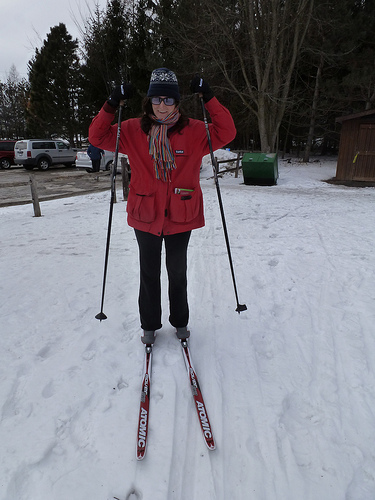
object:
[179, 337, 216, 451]
ski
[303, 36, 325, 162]
trunk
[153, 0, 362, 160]
tree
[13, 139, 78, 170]
car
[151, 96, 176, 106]
sunglasses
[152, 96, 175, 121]
face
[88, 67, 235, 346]
woman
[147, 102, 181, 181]
scarf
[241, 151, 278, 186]
trash bin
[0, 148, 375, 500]
snow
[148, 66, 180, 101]
hat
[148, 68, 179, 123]
head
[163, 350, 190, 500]
tracks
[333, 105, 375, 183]
building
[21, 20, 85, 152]
pine tree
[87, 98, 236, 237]
jacket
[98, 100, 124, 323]
ski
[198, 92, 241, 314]
ski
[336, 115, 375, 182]
wall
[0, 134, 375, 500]
ground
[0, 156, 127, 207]
parking lot